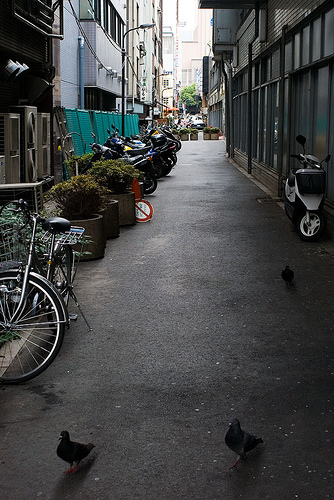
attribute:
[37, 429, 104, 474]
grey pigeon — dark grey 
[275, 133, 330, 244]
black motorcycle — white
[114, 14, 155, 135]
light pole — tall, metal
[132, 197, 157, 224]
red sign — white, prohibiting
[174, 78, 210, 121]
green tree — tall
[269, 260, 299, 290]
bird — black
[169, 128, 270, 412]
paved alley — urban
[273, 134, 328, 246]
parked scooter — white, row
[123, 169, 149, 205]
orange cone — traffic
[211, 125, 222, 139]
planter box — concrete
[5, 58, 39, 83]
three pipes — metallic